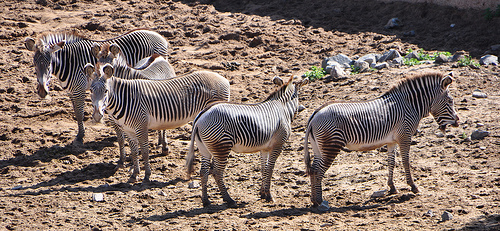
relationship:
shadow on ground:
[122, 202, 245, 222] [1, 1, 499, 228]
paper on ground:
[90, 190, 105, 205] [1, 1, 499, 228]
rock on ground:
[323, 50, 356, 83] [1, 1, 499, 228]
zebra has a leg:
[303, 68, 461, 211] [397, 135, 419, 197]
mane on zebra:
[388, 70, 444, 97] [303, 68, 461, 211]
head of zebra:
[429, 73, 461, 130] [303, 68, 461, 211]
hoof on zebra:
[411, 184, 420, 195] [303, 68, 461, 211]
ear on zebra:
[440, 74, 456, 91] [303, 68, 461, 211]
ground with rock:
[1, 1, 499, 228] [323, 50, 356, 83]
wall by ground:
[420, 0, 498, 12] [1, 1, 499, 228]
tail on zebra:
[180, 125, 197, 178] [303, 68, 461, 211]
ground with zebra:
[1, 1, 499, 228] [303, 68, 461, 211]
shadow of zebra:
[26, 178, 183, 198] [303, 68, 461, 211]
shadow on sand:
[1, 140, 85, 164] [2, 0, 499, 228]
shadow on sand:
[36, 161, 120, 181] [2, 0, 499, 228]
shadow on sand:
[26, 178, 183, 198] [2, 0, 499, 228]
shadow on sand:
[122, 202, 245, 222] [2, 0, 499, 228]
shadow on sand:
[235, 204, 375, 220] [2, 0, 499, 228]